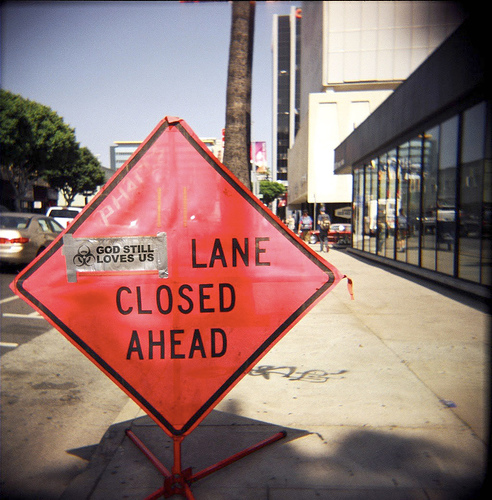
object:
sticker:
[62, 231, 166, 281]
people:
[293, 208, 313, 245]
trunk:
[219, 3, 261, 193]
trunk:
[10, 170, 27, 207]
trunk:
[61, 189, 75, 205]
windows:
[454, 98, 485, 286]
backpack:
[319, 211, 333, 232]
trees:
[0, 93, 103, 213]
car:
[0, 205, 70, 279]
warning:
[6, 113, 343, 444]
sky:
[0, 2, 279, 172]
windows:
[434, 116, 462, 276]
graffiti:
[247, 353, 349, 383]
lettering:
[114, 223, 270, 364]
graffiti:
[96, 162, 149, 234]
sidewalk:
[0, 235, 492, 498]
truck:
[44, 200, 78, 236]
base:
[123, 427, 286, 497]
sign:
[4, 111, 342, 443]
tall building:
[259, 13, 344, 214]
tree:
[223, 3, 256, 194]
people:
[316, 202, 330, 254]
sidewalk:
[9, 195, 84, 216]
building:
[329, 7, 490, 320]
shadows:
[64, 401, 486, 497]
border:
[192, 316, 284, 421]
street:
[3, 257, 52, 350]